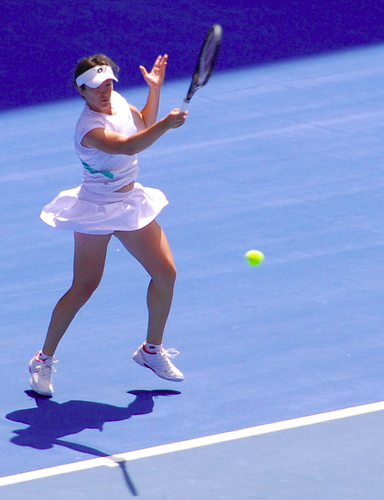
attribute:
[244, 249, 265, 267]
ball — green, flying, yellow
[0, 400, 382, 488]
line — white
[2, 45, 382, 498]
ground — blue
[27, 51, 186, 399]
woman — playing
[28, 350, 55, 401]
foot — white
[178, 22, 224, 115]
racket — black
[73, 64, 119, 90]
hat — white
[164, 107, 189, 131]
hand — raised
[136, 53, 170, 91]
hand — raised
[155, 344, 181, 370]
laces — white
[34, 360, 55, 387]
laces — white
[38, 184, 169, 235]
skirt — white, flying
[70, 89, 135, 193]
shirt — white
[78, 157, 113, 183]
stripe — green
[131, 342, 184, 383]
foot — white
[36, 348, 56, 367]
sock — white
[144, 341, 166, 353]
sock — white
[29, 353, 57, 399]
shoe — white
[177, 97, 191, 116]
grip — white